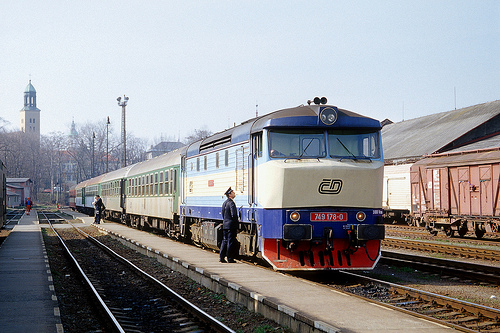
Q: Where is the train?
A: On the tracks.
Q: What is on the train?
A: Red white and blue.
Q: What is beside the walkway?
A: Tracks.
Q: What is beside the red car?
A: A white building.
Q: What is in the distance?
A: Trees.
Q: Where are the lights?
A: In the front of the train.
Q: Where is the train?
A: No the track.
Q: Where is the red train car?
A: On the right.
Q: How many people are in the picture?
A: Two.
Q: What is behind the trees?
A: Buildings.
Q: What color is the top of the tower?
A: Blue.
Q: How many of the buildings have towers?
A: Two.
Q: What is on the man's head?
A: A hat.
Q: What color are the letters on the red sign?
A: White.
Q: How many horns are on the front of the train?
A: Two.